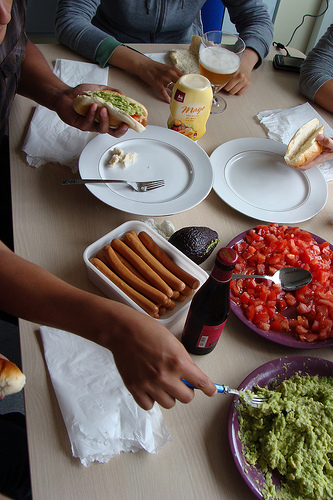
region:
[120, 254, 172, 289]
the snacks are brown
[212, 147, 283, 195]
the plate is white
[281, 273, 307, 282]
the spoon is grey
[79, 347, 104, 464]
the paper is white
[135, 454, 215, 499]
the table is cream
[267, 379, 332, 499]
the food is green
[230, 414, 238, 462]
the plate is purple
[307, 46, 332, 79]
the blouse is grey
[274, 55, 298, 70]
the phone is on a table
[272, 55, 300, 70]
the phone is a table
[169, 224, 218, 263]
an avocado that has been cut into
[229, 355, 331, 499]
guacamole in a purple plate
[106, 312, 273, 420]
a hand holding a fork with guacamole on it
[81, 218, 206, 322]
hotdog franks in a rectangular white dish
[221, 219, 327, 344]
small pieces of tomato in a purple plate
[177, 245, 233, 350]
a dark bottle with a red label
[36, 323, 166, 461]
folded white paper with jagged edges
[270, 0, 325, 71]
a black cable connected to a phone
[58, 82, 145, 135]
a hand holding a hotdog with guacamole on it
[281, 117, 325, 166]
an empty hotdog bun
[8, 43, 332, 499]
a wood dining table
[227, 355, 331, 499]
a round purple bowl of guacamole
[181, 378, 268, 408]
a fork in the guacamole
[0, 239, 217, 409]
a hand holding the fork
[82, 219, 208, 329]
a white container of hot dogs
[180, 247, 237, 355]
a bottled beverage on the table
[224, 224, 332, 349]
a round purple bowl of tomatoes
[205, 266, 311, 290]
a metal fork in the tomatoes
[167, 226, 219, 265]
an avocado on the table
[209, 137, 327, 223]
a round white plate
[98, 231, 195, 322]
Hot dogs in a bin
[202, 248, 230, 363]
Bottle of beer on a table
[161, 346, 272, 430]
Person holding a fork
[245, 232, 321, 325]
tomatoes on a plate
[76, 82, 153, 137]
person holding a hot dog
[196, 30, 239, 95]
Beer in a glass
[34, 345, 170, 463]
Bag on the table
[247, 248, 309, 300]
Spoon in the plate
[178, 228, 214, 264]
avocado on the table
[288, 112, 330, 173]
Person holding a bun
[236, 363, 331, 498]
guacamole on a plate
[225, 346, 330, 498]
the plate is purple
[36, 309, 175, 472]
paper on the table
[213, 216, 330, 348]
this plate is purple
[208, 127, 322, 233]
this plate is white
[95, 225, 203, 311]
hot dogs in a dish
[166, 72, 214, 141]
a jar of mayonnaise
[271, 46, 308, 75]
a phone on the table